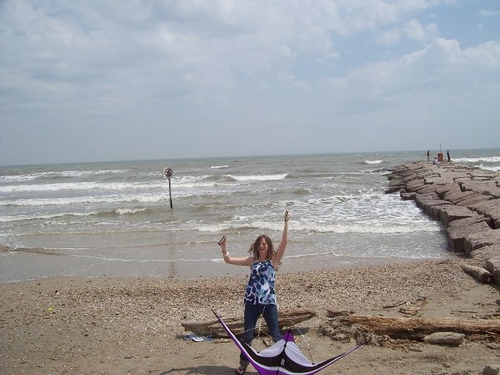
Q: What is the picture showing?
A: It is showing a shore.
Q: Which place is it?
A: It is a shore.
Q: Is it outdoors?
A: Yes, it is outdoors.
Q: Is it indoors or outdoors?
A: It is outdoors.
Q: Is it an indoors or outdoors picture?
A: It is outdoors.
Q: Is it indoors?
A: No, it is outdoors.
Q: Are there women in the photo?
A: Yes, there is a woman.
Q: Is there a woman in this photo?
A: Yes, there is a woman.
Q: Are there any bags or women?
A: Yes, there is a woman.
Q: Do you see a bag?
A: No, there are no bags.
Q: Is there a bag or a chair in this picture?
A: No, there are no bags or chairs.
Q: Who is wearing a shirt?
A: The woman is wearing a shirt.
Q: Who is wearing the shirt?
A: The woman is wearing a shirt.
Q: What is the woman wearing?
A: The woman is wearing a shirt.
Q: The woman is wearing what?
A: The woman is wearing a shirt.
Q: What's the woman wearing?
A: The woman is wearing a shirt.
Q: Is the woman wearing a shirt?
A: Yes, the woman is wearing a shirt.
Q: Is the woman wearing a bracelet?
A: No, the woman is wearing a shirt.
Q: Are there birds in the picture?
A: No, there are no birds.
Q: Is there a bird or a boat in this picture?
A: No, there are no birds or boats.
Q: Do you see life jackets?
A: No, there are no life jackets.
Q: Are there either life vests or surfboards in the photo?
A: No, there are no life vests or surfboards.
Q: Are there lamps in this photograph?
A: No, there are no lamps.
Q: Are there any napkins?
A: No, there are no napkins.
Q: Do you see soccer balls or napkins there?
A: No, there are no napkins or soccer balls.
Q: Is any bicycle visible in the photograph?
A: No, there are no bicycles.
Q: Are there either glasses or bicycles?
A: No, there are no bicycles or glasses.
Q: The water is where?
A: The water is on the shore.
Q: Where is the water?
A: The water is on the shore.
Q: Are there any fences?
A: No, there are no fences.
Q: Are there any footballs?
A: No, there are no footballs.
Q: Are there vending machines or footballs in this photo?
A: No, there are no footballs or vending machines.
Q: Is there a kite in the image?
A: Yes, there is a kite.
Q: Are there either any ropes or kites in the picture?
A: Yes, there is a kite.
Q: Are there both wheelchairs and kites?
A: No, there is a kite but no wheelchairs.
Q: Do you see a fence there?
A: No, there are no fences.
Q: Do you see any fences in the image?
A: No, there are no fences.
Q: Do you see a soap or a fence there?
A: No, there are no fences or soaps.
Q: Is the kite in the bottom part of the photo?
A: Yes, the kite is in the bottom of the image.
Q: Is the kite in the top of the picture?
A: No, the kite is in the bottom of the image.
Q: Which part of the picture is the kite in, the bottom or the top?
A: The kite is in the bottom of the image.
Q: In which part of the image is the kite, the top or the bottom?
A: The kite is in the bottom of the image.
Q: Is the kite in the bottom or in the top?
A: The kite is in the bottom of the image.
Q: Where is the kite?
A: The kite is on the ground.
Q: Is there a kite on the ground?
A: Yes, there is a kite on the ground.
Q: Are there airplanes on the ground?
A: No, there is a kite on the ground.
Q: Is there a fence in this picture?
A: No, there are no fences.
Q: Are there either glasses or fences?
A: No, there are no fences or glasses.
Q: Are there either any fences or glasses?
A: No, there are no fences or glasses.